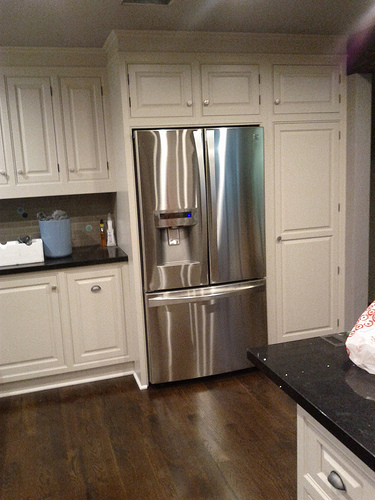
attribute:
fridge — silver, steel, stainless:
[127, 121, 278, 390]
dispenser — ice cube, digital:
[155, 210, 196, 269]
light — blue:
[181, 210, 193, 220]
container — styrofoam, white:
[0, 236, 49, 270]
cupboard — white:
[122, 55, 198, 121]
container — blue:
[37, 213, 74, 259]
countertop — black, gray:
[241, 323, 374, 471]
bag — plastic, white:
[341, 296, 375, 373]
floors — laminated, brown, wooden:
[2, 366, 295, 495]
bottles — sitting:
[94, 211, 117, 246]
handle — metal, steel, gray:
[186, 98, 194, 110]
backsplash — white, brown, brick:
[4, 193, 114, 249]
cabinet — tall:
[266, 117, 346, 343]